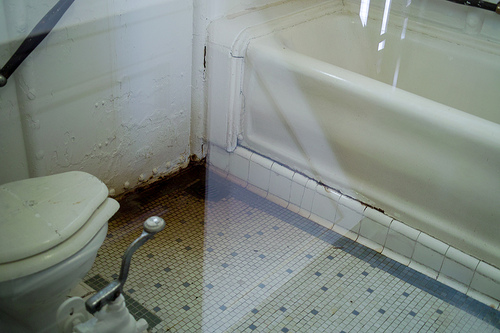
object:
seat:
[0, 169, 121, 301]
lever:
[84, 215, 167, 315]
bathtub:
[202, 0, 499, 271]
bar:
[0, 0, 76, 88]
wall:
[110, 6, 182, 67]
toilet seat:
[0, 170, 121, 331]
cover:
[0, 169, 108, 264]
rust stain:
[126, 158, 205, 198]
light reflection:
[84, 281, 125, 313]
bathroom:
[0, 0, 500, 331]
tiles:
[362, 218, 499, 331]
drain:
[195, 181, 221, 200]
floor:
[203, 271, 385, 327]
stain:
[167, 203, 267, 245]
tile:
[239, 249, 500, 333]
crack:
[234, 139, 392, 214]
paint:
[68, 26, 164, 144]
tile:
[205, 146, 317, 213]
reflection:
[200, 0, 419, 333]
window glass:
[339, 0, 416, 101]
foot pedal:
[55, 215, 166, 333]